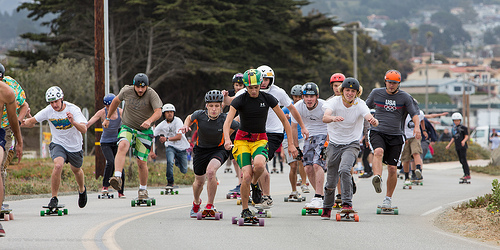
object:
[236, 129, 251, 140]
bob marley colors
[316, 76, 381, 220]
man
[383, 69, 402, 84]
helmet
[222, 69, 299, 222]
people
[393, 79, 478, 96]
houses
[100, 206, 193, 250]
line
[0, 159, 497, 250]
road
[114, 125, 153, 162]
shorts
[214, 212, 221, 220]
wheels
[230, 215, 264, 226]
skateboard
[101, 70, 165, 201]
person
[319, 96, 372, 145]
shirt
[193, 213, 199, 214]
shoe strings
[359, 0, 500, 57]
city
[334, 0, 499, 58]
hill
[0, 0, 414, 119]
trees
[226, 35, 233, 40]
leaves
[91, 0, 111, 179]
pole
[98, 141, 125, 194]
jeans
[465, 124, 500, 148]
truck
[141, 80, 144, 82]
slots